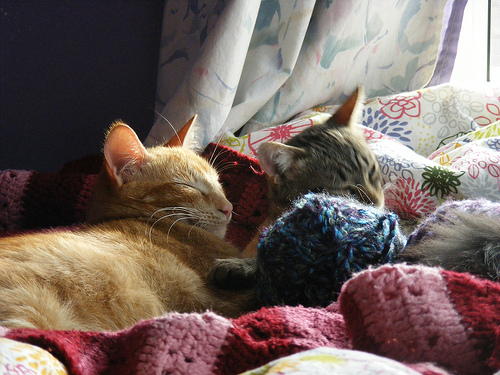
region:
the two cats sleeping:
[1, 85, 499, 335]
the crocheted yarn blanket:
[9, 261, 499, 371]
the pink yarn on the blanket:
[371, 282, 445, 350]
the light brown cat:
[0, 112, 230, 364]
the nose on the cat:
[218, 198, 233, 217]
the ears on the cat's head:
[99, 111, 203, 185]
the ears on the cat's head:
[257, 84, 363, 174]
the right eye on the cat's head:
[168, 175, 205, 197]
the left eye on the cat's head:
[363, 159, 379, 184]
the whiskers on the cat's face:
[142, 200, 215, 249]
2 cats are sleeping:
[57, 66, 467, 368]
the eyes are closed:
[142, 162, 234, 194]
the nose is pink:
[209, 195, 244, 224]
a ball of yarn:
[262, 182, 415, 292]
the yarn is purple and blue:
[248, 184, 416, 289]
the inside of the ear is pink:
[73, 109, 156, 186]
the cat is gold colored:
[5, 102, 236, 324]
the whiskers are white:
[134, 191, 231, 231]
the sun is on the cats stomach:
[10, 222, 153, 307]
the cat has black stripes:
[288, 120, 370, 202]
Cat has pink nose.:
[216, 191, 238, 226]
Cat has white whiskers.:
[154, 203, 198, 228]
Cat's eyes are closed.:
[175, 171, 227, 196]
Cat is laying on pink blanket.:
[44, 161, 188, 321]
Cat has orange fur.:
[21, 122, 196, 305]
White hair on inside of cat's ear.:
[273, 149, 293, 161]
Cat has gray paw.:
[223, 233, 259, 297]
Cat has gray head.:
[285, 122, 410, 204]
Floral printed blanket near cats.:
[371, 85, 498, 198]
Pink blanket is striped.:
[156, 317, 402, 348]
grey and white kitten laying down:
[252, 81, 388, 255]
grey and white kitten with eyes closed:
[244, 84, 402, 276]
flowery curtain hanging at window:
[153, 0, 494, 145]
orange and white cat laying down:
[6, 101, 250, 343]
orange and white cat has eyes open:
[4, 102, 251, 339]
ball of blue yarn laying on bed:
[257, 192, 401, 310]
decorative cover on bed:
[217, 70, 497, 239]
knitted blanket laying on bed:
[0, 144, 496, 374]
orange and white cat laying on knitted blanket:
[0, 114, 497, 374]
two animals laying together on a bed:
[3, 86, 482, 328]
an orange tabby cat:
[1, 113, 234, 316]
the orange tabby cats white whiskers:
[145, 203, 205, 247]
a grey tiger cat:
[257, 87, 386, 207]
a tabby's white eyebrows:
[206, 135, 236, 177]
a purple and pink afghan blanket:
[1, 263, 498, 373]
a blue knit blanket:
[257, 191, 400, 298]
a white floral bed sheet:
[382, 80, 497, 217]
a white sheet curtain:
[151, 1, 498, 89]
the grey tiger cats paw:
[206, 255, 259, 292]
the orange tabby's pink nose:
[218, 198, 233, 220]